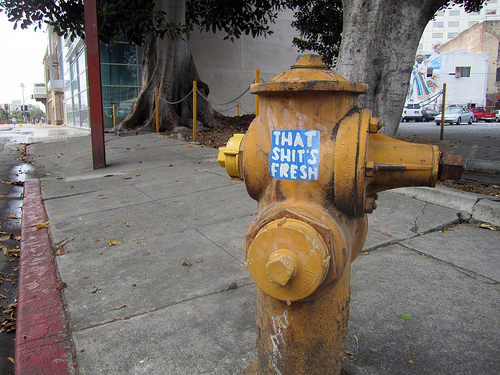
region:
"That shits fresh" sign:
[269, 128, 326, 185]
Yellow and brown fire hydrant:
[203, 43, 467, 372]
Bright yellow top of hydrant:
[216, 131, 251, 185]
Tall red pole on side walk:
[76, 0, 117, 172]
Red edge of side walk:
[14, 175, 66, 373]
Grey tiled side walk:
[40, 120, 498, 372]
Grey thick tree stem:
[334, 0, 499, 170]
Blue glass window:
[65, 25, 137, 125]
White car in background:
[436, 106, 474, 124]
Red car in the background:
[471, 105, 493, 122]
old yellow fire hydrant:
[208, 47, 470, 374]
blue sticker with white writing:
[266, 124, 323, 184]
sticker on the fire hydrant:
[268, 126, 320, 181]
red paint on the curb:
[12, 123, 83, 374]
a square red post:
[81, 0, 108, 170]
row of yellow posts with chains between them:
[17, 71, 451, 178]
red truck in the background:
[464, 100, 498, 124]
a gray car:
[434, 103, 474, 128]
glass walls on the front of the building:
[58, 17, 148, 134]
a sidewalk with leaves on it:
[23, 114, 498, 373]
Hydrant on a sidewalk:
[206, 47, 463, 373]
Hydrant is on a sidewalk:
[205, 43, 470, 373]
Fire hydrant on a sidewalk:
[215, 47, 467, 372]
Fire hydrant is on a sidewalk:
[215, 47, 470, 372]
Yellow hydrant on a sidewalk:
[212, 43, 468, 373]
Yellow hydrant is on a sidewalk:
[206, 50, 472, 373]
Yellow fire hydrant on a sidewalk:
[207, 46, 473, 373]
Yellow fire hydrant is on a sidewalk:
[216, 45, 463, 373]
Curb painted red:
[13, 122, 87, 372]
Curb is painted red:
[12, 120, 81, 372]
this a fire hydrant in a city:
[52, 34, 482, 327]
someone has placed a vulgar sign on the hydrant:
[233, 109, 355, 206]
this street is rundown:
[15, 123, 221, 368]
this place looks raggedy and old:
[20, 48, 477, 304]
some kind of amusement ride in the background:
[417, 59, 446, 114]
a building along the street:
[37, 26, 139, 132]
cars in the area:
[444, 97, 490, 134]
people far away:
[6, 109, 43, 134]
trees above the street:
[4, 1, 339, 44]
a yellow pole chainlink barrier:
[107, 83, 263, 132]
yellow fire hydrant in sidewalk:
[216, 55, 438, 373]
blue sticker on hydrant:
[270, 130, 320, 181]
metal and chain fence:
[109, 69, 446, 166]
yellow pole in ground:
[193, 80, 196, 144]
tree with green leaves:
[1, 0, 275, 130]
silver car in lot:
[436, 106, 475, 125]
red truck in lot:
[471, 105, 495, 120]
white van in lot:
[402, 101, 424, 121]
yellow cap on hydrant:
[216, 130, 242, 178]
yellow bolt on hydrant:
[266, 254, 295, 284]